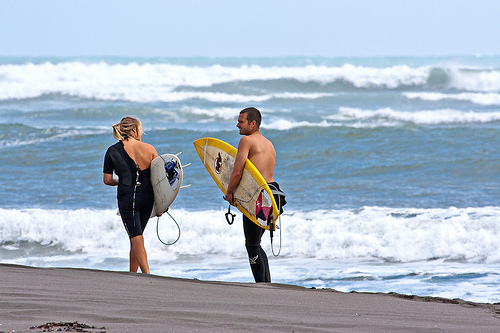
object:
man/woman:
[103, 106, 276, 282]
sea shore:
[279, 286, 499, 332]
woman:
[102, 115, 193, 274]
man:
[193, 106, 287, 283]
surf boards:
[190, 133, 281, 231]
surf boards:
[148, 150, 192, 219]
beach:
[0, 268, 108, 332]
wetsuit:
[103, 139, 154, 236]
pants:
[241, 180, 287, 283]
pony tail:
[112, 120, 129, 139]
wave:
[309, 212, 461, 264]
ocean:
[7, 58, 198, 107]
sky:
[309, 11, 498, 42]